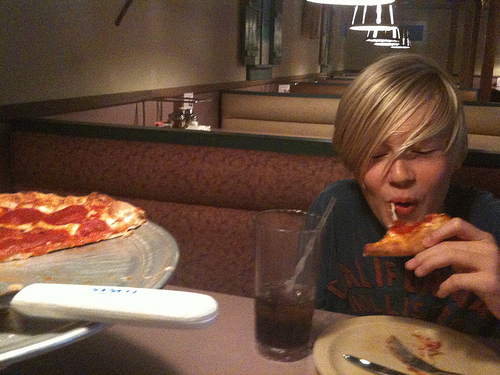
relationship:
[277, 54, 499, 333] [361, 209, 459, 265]
boy eating pizza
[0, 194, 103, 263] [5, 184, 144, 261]
pepperonis on pizza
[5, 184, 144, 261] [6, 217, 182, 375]
pizza on platter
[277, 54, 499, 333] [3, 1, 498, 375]
boy in pizza parlor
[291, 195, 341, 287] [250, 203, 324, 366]
straw in drink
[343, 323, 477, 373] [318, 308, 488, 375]
utensils on plate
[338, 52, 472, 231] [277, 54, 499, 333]
head of boy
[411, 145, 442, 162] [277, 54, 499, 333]
eye of boy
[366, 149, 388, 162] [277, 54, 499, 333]
eye of boy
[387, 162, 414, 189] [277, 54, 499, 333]
nose of boy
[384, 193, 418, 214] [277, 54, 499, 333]
mouth of boy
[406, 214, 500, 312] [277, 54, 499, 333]
hand of boy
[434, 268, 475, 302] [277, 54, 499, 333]
finger of boy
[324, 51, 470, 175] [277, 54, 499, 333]
hair of boy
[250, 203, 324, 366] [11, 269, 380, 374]
drink on table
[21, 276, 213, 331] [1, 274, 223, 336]
handle of pizza server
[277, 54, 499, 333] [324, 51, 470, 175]
boy with hair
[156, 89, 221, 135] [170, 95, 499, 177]
condiments on a table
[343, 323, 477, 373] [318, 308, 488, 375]
utensils on a plate